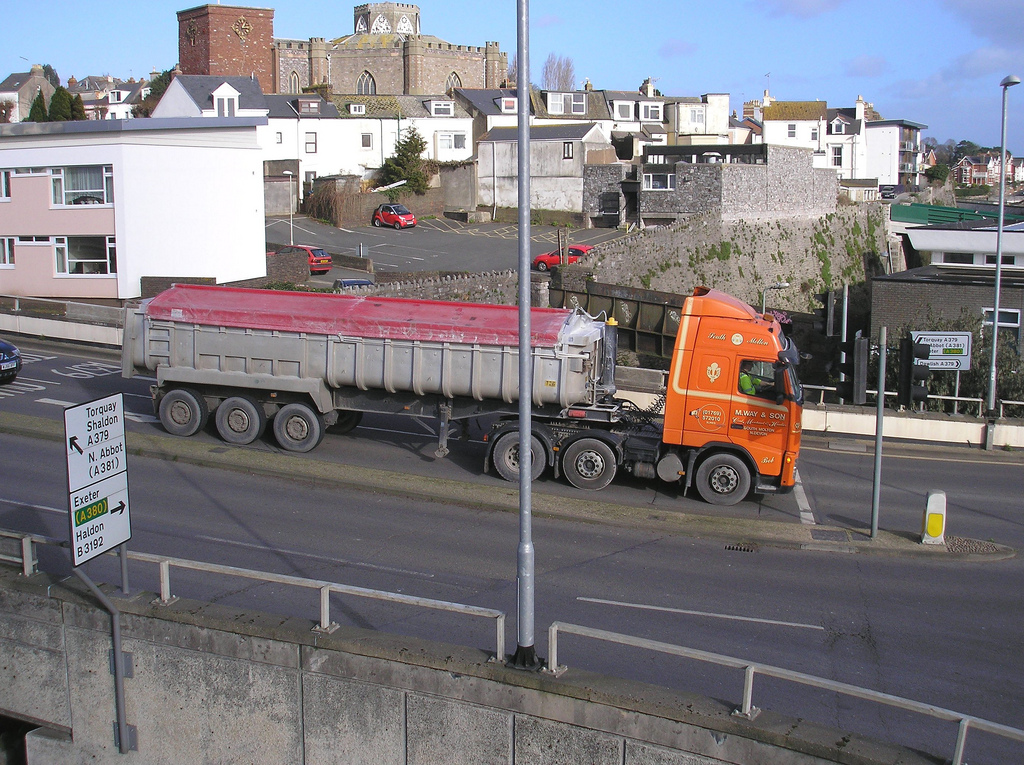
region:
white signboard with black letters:
[59, 384, 129, 584]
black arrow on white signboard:
[60, 420, 84, 458]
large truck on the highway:
[126, 271, 807, 509]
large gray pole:
[511, 8, 535, 673]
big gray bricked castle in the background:
[165, 3, 508, 98]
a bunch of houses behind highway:
[0, 78, 923, 313]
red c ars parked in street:
[278, 197, 596, 305]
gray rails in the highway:
[0, 523, 1016, 761]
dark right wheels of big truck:
[155, 379, 756, 513]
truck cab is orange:
[669, 275, 805, 501]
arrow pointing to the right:
[105, 497, 137, 524]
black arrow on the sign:
[65, 433, 89, 457]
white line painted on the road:
[574, 583, 843, 648]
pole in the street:
[870, 316, 899, 552]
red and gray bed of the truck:
[122, 273, 617, 471]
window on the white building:
[302, 127, 321, 160]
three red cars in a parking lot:
[282, 196, 603, 288]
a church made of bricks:
[167, 4, 544, 107]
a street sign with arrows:
[54, 386, 165, 580]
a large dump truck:
[108, 262, 839, 503]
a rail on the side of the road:
[149, 540, 568, 673]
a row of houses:
[183, 72, 756, 194]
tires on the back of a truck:
[142, 379, 336, 453]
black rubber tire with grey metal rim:
[695, 452, 750, 504]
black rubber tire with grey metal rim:
[562, 433, 617, 487]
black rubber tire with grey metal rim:
[492, 430, 546, 478]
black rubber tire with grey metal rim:
[214, 395, 265, 443]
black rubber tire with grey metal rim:
[160, 386, 206, 432]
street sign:
[62, 391, 133, 566]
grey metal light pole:
[512, 0, 542, 667]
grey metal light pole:
[986, 76, 1019, 412]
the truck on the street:
[104, 258, 813, 537]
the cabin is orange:
[663, 271, 834, 532]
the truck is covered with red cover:
[104, 258, 636, 497]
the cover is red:
[138, 283, 588, 361]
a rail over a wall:
[0, 524, 517, 668]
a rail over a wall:
[543, 599, 1019, 761]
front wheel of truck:
[686, 448, 767, 526]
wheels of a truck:
[486, 423, 641, 497]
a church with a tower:
[269, 6, 516, 121]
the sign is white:
[51, 371, 143, 580]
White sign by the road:
[59, 400, 152, 574]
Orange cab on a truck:
[659, 292, 806, 493]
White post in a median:
[906, 484, 955, 554]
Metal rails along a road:
[537, 620, 987, 763]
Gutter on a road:
[723, 536, 765, 560]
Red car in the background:
[369, 197, 423, 239]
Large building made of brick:
[278, 7, 512, 102]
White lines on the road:
[575, 587, 828, 644]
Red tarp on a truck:
[154, 279, 576, 350]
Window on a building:
[43, 162, 126, 219]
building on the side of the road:
[0, 80, 285, 316]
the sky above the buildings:
[20, 1, 1019, 157]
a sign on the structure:
[48, 382, 150, 570]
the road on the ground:
[8, 287, 1011, 752]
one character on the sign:
[71, 541, 82, 561]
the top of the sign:
[49, 373, 151, 443]